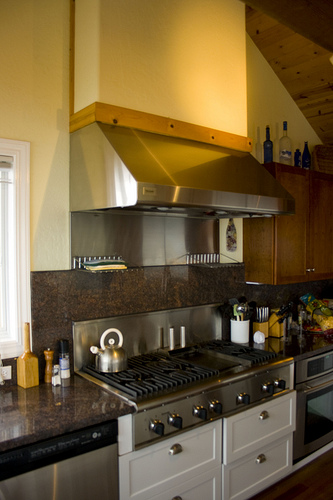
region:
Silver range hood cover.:
[66, 123, 295, 215]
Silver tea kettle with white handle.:
[86, 329, 126, 373]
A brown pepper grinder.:
[41, 347, 53, 384]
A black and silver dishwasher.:
[0, 416, 117, 498]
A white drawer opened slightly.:
[221, 390, 297, 466]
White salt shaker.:
[50, 366, 62, 387]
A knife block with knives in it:
[268, 300, 293, 338]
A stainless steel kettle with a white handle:
[89, 326, 127, 373]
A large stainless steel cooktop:
[72, 302, 294, 451]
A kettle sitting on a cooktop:
[81, 326, 219, 397]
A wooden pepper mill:
[42, 346, 53, 382]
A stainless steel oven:
[294, 347, 330, 465]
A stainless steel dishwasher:
[1, 418, 119, 499]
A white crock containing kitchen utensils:
[228, 294, 250, 342]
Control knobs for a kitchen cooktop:
[144, 376, 285, 434]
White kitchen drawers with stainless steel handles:
[220, 390, 297, 498]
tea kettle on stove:
[89, 327, 128, 372]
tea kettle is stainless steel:
[89, 328, 127, 372]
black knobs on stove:
[150, 374, 285, 435]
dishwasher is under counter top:
[0, 416, 121, 498]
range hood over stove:
[69, 120, 295, 269]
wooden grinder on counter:
[44, 345, 54, 381]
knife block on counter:
[268, 299, 293, 337]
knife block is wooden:
[269, 299, 292, 336]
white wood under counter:
[118, 388, 332, 498]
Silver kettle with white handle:
[90, 327, 128, 374]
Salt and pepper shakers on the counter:
[42, 340, 73, 386]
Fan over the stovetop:
[70, 122, 295, 219]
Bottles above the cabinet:
[264, 118, 312, 165]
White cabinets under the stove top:
[119, 388, 297, 498]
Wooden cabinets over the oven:
[244, 162, 331, 287]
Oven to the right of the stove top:
[288, 345, 330, 461]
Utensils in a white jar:
[229, 301, 250, 343]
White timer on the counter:
[253, 328, 265, 345]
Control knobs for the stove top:
[146, 375, 289, 436]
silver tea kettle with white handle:
[88, 327, 127, 374]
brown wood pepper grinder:
[41, 345, 55, 383]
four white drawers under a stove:
[117, 386, 294, 498]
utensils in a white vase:
[228, 291, 251, 342]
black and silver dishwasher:
[2, 417, 120, 498]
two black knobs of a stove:
[146, 411, 183, 436]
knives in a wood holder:
[267, 297, 294, 337]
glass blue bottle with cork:
[260, 122, 274, 164]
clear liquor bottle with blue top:
[277, 115, 293, 168]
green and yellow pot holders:
[83, 257, 128, 273]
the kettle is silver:
[89, 329, 128, 372]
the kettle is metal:
[96, 329, 127, 374]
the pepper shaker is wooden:
[40, 349, 52, 384]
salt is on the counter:
[51, 365, 60, 386]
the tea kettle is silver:
[90, 326, 126, 372]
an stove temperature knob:
[150, 418, 162, 434]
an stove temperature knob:
[167, 414, 180, 426]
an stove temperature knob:
[192, 405, 207, 418]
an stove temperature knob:
[210, 398, 222, 414]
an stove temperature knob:
[237, 392, 251, 404]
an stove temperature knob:
[263, 381, 273, 395]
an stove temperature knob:
[274, 378, 285, 389]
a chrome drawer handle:
[168, 444, 182, 454]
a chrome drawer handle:
[260, 409, 269, 418]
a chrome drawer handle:
[254, 454, 264, 462]